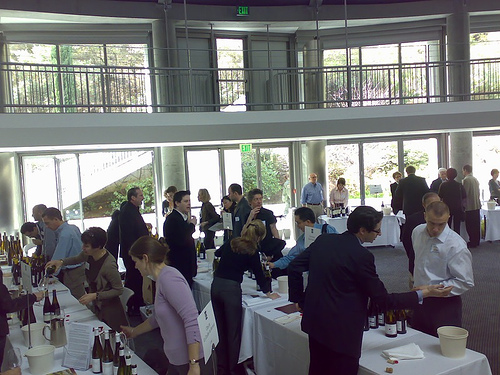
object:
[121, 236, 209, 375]
woman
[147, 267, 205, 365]
sweater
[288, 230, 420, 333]
jacket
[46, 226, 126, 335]
woman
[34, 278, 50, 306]
glass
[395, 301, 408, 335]
bottles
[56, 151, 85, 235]
door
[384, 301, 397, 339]
bottles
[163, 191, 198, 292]
man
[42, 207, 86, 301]
man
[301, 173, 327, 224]
man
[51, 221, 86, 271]
shirt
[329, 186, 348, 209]
shirt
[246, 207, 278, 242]
shirt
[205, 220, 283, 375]
woman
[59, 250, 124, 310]
sweater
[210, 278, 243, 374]
pants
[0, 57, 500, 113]
railing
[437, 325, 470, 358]
buckets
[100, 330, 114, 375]
wine bottle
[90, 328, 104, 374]
wine bottle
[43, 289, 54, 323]
wine bottle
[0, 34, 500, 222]
outside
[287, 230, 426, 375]
suite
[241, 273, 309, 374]
white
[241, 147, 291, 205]
bush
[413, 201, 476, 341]
man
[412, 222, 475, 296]
dress shirt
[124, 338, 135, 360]
glass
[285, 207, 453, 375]
man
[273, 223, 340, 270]
shirt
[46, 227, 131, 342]
she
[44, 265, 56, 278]
wine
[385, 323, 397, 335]
label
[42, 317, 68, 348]
pitcher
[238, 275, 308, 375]
tablecloth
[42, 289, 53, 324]
wine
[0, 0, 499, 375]
wine tasting